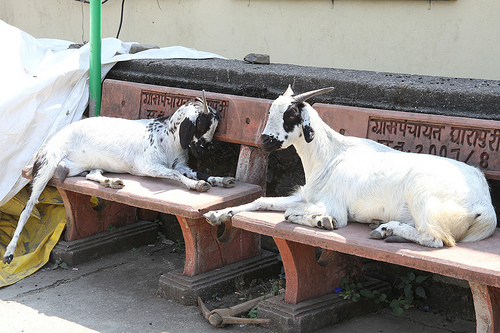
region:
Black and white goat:
[202, 79, 497, 250]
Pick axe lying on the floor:
[191, 289, 287, 329]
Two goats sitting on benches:
[0, 80, 499, 263]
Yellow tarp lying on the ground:
[0, 181, 66, 286]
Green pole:
[85, 0, 102, 117]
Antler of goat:
[290, 83, 334, 103]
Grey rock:
[242, 51, 269, 66]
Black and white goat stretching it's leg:
[0, 88, 238, 267]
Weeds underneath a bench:
[333, 267, 430, 317]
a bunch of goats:
[47, 79, 472, 267]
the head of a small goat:
[248, 79, 320, 167]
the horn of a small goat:
[292, 83, 339, 105]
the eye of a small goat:
[275, 98, 313, 126]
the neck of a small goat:
[301, 116, 336, 164]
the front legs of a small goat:
[222, 185, 327, 242]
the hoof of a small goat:
[202, 203, 232, 221]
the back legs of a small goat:
[380, 211, 454, 252]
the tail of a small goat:
[474, 195, 498, 232]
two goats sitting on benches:
[41, 60, 482, 320]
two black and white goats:
[81, 70, 436, 270]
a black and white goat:
[248, 82, 498, 288]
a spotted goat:
[30, 67, 248, 219]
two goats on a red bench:
[46, 49, 472, 311]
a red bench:
[48, 58, 498, 281]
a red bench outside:
[51, 50, 476, 325]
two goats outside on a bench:
[32, 52, 459, 332]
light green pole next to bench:
[85, 0, 106, 114]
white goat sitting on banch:
[211, 83, 498, 250]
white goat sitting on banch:
[5, 95, 235, 258]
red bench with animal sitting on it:
[238, 94, 498, 311]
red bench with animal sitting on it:
[57, 79, 272, 290]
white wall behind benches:
[128, 2, 498, 83]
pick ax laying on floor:
[188, 287, 279, 329]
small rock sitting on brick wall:
[241, 50, 275, 77]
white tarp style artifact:
[0, 17, 225, 103]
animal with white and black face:
[160, 90, 222, 153]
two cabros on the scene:
[9, 85, 494, 283]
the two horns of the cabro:
[285, 84, 332, 97]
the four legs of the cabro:
[206, 190, 451, 247]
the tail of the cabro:
[470, 209, 497, 240]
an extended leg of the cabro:
[6, 166, 53, 269]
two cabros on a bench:
[0, 83, 499, 264]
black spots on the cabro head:
[178, 103, 218, 153]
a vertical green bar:
[89, 0, 101, 115]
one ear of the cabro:
[299, 106, 317, 140]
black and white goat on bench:
[202, 76, 498, 260]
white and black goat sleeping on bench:
[5, 84, 242, 274]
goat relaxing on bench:
[201, 75, 498, 292]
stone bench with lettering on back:
[231, 95, 498, 330]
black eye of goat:
[282, 100, 304, 140]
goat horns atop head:
[281, 79, 333, 106]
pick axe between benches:
[188, 285, 289, 331]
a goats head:
[253, 65, 330, 150]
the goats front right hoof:
[204, 204, 232, 225]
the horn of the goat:
[293, 81, 337, 106]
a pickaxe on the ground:
[188, 261, 292, 328]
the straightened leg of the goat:
[10, 138, 66, 277]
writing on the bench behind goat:
[367, 107, 498, 166]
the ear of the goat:
[298, 99, 320, 141]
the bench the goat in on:
[43, 56, 284, 308]